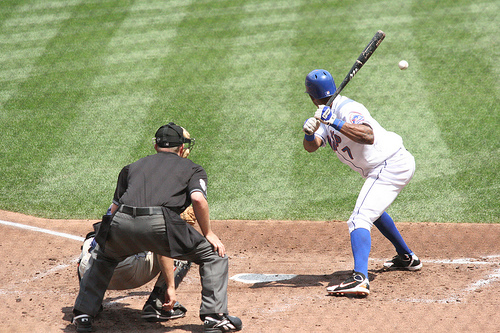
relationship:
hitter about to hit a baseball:
[302, 67, 422, 294] [398, 58, 410, 70]